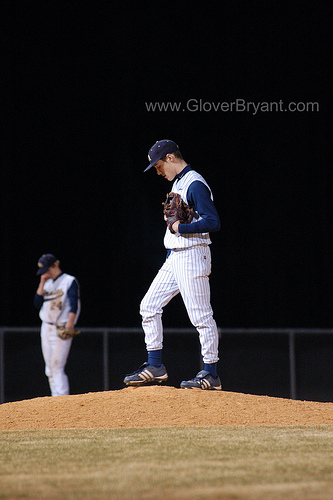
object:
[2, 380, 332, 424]
pitcher's mound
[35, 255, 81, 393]
baseball player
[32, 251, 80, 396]
player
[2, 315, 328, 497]
ball field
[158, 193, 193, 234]
baseball mitt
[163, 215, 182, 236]
player's hand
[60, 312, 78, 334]
player's hand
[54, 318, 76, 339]
baseball mitt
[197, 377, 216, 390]
logo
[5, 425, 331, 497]
field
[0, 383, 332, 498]
mound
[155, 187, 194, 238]
mitt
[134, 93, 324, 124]
lettering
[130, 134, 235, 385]
man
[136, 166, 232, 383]
uniform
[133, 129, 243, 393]
player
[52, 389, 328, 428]
hill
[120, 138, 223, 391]
pitcher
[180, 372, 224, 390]
shoe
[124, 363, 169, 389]
shoe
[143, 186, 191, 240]
glove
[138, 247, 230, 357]
pants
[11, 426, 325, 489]
grass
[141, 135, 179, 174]
hat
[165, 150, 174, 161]
ear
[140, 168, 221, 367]
uniform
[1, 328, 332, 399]
fence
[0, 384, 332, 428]
mound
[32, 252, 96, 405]
men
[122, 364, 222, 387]
sneakers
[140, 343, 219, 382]
socks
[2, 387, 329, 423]
dirt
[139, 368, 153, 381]
stripes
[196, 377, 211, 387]
stripes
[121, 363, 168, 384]
sneaker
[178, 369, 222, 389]
sneaker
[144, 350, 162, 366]
sock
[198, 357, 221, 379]
sock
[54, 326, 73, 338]
mitt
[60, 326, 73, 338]
hand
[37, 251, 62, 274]
cap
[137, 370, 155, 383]
logo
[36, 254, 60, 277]
head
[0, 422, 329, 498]
turf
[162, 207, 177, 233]
hand